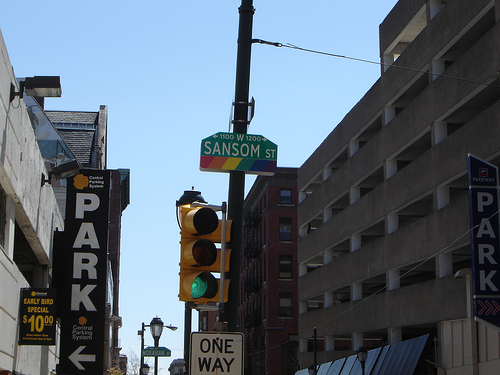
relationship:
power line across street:
[246, 28, 387, 68] [2, 7, 493, 373]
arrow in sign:
[63, 337, 96, 373] [58, 164, 118, 374]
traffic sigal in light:
[171, 188, 231, 317] [188, 276, 218, 305]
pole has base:
[142, 310, 166, 373] [134, 339, 172, 362]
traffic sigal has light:
[171, 188, 231, 317] [185, 274, 214, 304]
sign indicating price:
[18, 285, 58, 346] [21, 310, 53, 330]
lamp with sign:
[148, 319, 173, 373] [137, 345, 175, 358]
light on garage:
[16, 75, 64, 102] [13, 125, 43, 276]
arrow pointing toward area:
[63, 337, 96, 373] [6, 160, 24, 369]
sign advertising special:
[18, 285, 58, 346] [23, 297, 55, 342]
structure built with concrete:
[294, 157, 462, 312] [364, 192, 399, 210]